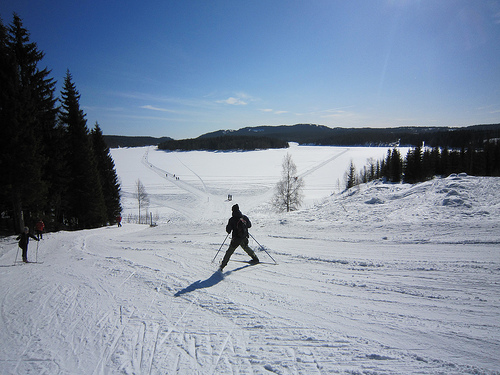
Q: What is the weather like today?
A: It is clear.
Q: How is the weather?
A: It is clear.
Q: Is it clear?
A: Yes, it is clear.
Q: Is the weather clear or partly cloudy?
A: It is clear.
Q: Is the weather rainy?
A: No, it is clear.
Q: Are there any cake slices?
A: No, there are no cake slices.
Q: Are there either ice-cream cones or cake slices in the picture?
A: No, there are no cake slices or ice-cream cones.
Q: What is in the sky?
A: The clouds are in the sky.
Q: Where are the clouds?
A: The clouds are in the sky.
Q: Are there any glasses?
A: No, there are no glasses.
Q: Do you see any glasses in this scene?
A: No, there are no glasses.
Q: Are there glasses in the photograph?
A: No, there are no glasses.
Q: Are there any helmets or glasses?
A: No, there are no glasses or helmets.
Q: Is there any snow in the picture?
A: Yes, there is snow.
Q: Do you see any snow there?
A: Yes, there is snow.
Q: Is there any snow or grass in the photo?
A: Yes, there is snow.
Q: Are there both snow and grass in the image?
A: No, there is snow but no grass.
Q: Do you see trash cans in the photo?
A: No, there are no trash cans.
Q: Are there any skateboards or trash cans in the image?
A: No, there are no trash cans or skateboards.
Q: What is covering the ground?
A: The snow is covering the ground.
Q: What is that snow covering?
A: The snow is covering the ground.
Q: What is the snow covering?
A: The snow is covering the ground.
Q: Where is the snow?
A: The snow is on the ground.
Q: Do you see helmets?
A: No, there are no helmets.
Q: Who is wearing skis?
A: The man is wearing skis.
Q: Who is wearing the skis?
A: The man is wearing skis.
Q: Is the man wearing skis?
A: Yes, the man is wearing skis.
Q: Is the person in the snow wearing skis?
A: Yes, the man is wearing skis.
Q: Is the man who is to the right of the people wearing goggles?
A: No, the man is wearing skis.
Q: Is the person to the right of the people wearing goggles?
A: No, the man is wearing skis.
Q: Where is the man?
A: The man is in the snow.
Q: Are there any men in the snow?
A: Yes, there is a man in the snow.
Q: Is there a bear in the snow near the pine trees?
A: No, there is a man in the snow.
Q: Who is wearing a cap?
A: The man is wearing a cap.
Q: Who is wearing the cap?
A: The man is wearing a cap.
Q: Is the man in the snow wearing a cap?
A: Yes, the man is wearing a cap.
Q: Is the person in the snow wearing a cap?
A: Yes, the man is wearing a cap.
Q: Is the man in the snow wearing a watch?
A: No, the man is wearing a cap.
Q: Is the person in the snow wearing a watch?
A: No, the man is wearing a cap.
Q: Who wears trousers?
A: The man wears trousers.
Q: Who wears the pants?
A: The man wears trousers.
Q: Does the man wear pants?
A: Yes, the man wears pants.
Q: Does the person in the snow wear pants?
A: Yes, the man wears pants.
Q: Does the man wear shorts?
A: No, the man wears pants.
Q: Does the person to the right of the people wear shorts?
A: No, the man wears pants.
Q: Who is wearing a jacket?
A: The man is wearing a jacket.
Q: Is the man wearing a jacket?
A: Yes, the man is wearing a jacket.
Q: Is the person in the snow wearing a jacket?
A: Yes, the man is wearing a jacket.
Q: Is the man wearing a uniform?
A: No, the man is wearing a jacket.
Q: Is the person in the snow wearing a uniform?
A: No, the man is wearing a jacket.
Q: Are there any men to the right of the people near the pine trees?
A: Yes, there is a man to the right of the people.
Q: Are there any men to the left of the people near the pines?
A: No, the man is to the right of the people.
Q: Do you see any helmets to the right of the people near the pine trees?
A: No, there is a man to the right of the people.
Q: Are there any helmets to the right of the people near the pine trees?
A: No, there is a man to the right of the people.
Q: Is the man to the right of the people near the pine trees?
A: Yes, the man is to the right of the people.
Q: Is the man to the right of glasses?
A: No, the man is to the right of the people.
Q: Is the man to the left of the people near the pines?
A: No, the man is to the right of the people.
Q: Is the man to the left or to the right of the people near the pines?
A: The man is to the right of the people.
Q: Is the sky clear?
A: Yes, the sky is clear.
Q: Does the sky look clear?
A: Yes, the sky is clear.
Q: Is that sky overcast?
A: No, the sky is clear.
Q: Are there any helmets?
A: No, there are no helmets.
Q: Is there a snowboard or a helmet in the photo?
A: No, there are no helmets or snowboards.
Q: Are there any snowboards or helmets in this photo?
A: No, there are no helmets or snowboards.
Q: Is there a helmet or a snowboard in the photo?
A: No, there are no helmets or snowboards.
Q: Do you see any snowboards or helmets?
A: No, there are no helmets or snowboards.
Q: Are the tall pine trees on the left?
A: Yes, the pines are on the left of the image.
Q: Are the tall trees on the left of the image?
A: Yes, the pines are on the left of the image.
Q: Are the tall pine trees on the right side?
A: No, the pines are on the left of the image.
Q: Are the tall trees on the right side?
A: No, the pines are on the left of the image.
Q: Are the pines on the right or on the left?
A: The pines are on the left of the image.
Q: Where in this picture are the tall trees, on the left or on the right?
A: The pines are on the left of the image.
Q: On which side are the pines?
A: The pines are on the left of the image.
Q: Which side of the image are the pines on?
A: The pines are on the left of the image.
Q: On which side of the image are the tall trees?
A: The pines are on the left of the image.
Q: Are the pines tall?
A: Yes, the pines are tall.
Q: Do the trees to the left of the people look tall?
A: Yes, the pine trees are tall.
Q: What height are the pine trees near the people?
A: The pines are tall.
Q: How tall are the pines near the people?
A: The pines are tall.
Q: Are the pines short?
A: No, the pines are tall.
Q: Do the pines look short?
A: No, the pines are tall.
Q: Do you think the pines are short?
A: No, the pines are tall.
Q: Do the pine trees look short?
A: No, the pine trees are tall.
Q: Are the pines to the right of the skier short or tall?
A: The pine trees are tall.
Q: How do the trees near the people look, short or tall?
A: The pine trees are tall.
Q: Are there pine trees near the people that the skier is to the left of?
A: Yes, there are pine trees near the people.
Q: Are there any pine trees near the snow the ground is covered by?
A: Yes, there are pine trees near the snow.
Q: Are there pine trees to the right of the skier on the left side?
A: Yes, there are pine trees to the right of the skier.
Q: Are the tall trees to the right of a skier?
A: Yes, the pine trees are to the right of a skier.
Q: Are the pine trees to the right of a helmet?
A: No, the pine trees are to the right of a skier.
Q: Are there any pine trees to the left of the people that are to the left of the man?
A: Yes, there are pine trees to the left of the people.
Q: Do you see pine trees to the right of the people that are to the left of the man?
A: No, the pine trees are to the left of the people.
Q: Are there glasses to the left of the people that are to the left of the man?
A: No, there are pine trees to the left of the people.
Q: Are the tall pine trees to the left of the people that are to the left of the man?
A: Yes, the pine trees are to the left of the people.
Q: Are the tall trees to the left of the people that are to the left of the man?
A: Yes, the pine trees are to the left of the people.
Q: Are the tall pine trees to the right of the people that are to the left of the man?
A: No, the pine trees are to the left of the people.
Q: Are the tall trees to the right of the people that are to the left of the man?
A: No, the pine trees are to the left of the people.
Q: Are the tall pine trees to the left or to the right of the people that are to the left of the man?
A: The pine trees are to the left of the people.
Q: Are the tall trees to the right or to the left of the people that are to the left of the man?
A: The pine trees are to the left of the people.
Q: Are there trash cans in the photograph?
A: No, there are no trash cans.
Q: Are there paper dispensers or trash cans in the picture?
A: No, there are no trash cans or paper dispensers.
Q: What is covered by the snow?
A: The ground is covered by the snow.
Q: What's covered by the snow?
A: The ground is covered by the snow.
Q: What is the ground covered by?
A: The ground is covered by the snow.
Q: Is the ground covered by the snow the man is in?
A: Yes, the ground is covered by the snow.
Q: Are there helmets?
A: No, there are no helmets.